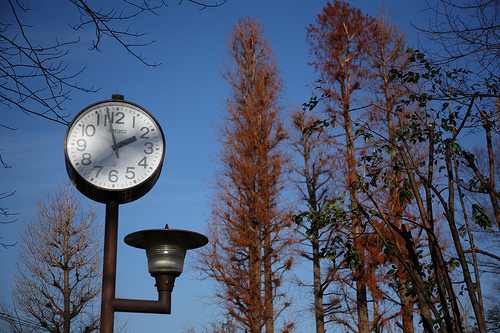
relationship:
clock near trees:
[62, 92, 166, 204] [214, 1, 500, 332]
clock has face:
[62, 92, 166, 204] [68, 105, 161, 182]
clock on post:
[49, 92, 184, 212] [85, 200, 129, 327]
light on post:
[119, 222, 211, 316] [85, 200, 129, 327]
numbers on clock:
[77, 111, 151, 180] [62, 92, 166, 204]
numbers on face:
[77, 111, 151, 180] [68, 105, 161, 182]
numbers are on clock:
[77, 111, 151, 180] [62, 92, 166, 204]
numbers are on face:
[77, 111, 151, 180] [68, 105, 161, 182]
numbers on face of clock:
[77, 111, 151, 180] [62, 92, 166, 204]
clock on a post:
[49, 92, 184, 212] [85, 200, 129, 327]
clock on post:
[62, 92, 166, 204] [85, 200, 129, 327]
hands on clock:
[105, 110, 140, 153] [62, 92, 166, 204]